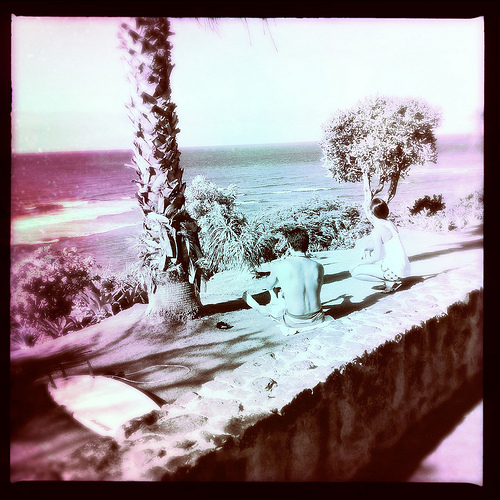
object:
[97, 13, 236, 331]
tree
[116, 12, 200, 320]
shore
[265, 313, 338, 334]
shirt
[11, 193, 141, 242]
waves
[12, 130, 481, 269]
ocean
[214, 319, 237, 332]
sandal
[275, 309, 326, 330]
shorts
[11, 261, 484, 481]
wall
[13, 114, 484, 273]
water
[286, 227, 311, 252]
hair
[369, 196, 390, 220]
hair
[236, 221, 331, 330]
person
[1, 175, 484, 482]
beach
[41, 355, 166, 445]
surfboad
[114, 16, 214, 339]
palm tree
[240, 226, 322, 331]
boy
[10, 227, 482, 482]
sand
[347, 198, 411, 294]
girl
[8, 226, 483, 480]
ground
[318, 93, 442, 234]
tree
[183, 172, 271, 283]
tree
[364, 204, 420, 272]
top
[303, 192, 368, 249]
bush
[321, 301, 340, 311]
sunglasses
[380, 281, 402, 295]
flip-flops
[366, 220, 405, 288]
suit